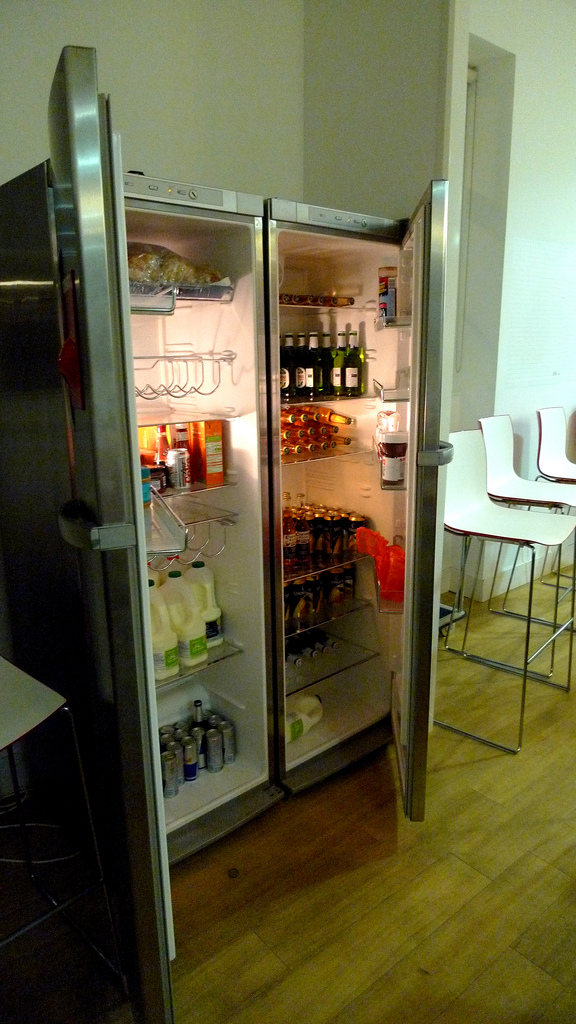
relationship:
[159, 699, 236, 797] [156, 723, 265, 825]
beer on shelf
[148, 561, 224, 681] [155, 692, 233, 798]
jug above cans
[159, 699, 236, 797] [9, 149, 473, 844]
beer in fridge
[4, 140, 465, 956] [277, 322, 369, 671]
refrigerator full of beer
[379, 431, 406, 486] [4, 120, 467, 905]
jar in fridge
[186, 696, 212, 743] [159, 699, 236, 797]
beer surrounded by beer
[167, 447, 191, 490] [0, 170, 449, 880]
diet coke in a fridge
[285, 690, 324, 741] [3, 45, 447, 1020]
jug in bottom of fridge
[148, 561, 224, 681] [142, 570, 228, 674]
jug in jug